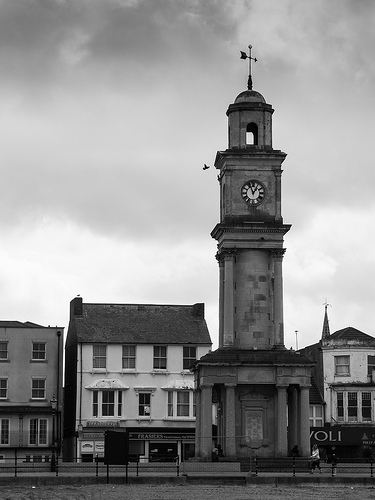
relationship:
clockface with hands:
[241, 177, 265, 204] [248, 184, 254, 195]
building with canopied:
[65, 294, 213, 462] [188, 288, 206, 327]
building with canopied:
[65, 294, 213, 462] [65, 291, 88, 323]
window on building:
[331, 388, 374, 426] [301, 298, 373, 453]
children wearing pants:
[310, 444, 324, 474] [312, 458, 322, 469]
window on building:
[93, 344, 107, 368] [65, 295, 211, 460]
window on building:
[135, 389, 153, 420] [65, 295, 211, 460]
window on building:
[181, 341, 198, 371] [65, 295, 211, 460]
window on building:
[90, 390, 121, 416] [65, 295, 211, 460]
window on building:
[152, 345, 176, 373] [65, 295, 211, 460]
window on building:
[160, 373, 200, 428] [65, 299, 241, 455]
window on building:
[84, 337, 116, 370] [0, 320, 62, 461]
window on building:
[0, 342, 7, 359] [0, 320, 62, 461]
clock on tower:
[238, 180, 279, 212] [192, 80, 325, 473]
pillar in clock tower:
[273, 384, 291, 457] [193, 46, 310, 471]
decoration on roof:
[316, 297, 339, 337] [310, 313, 373, 354]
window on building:
[155, 346, 167, 371] [65, 295, 211, 460]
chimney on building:
[64, 294, 104, 331] [65, 295, 211, 460]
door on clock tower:
[242, 396, 267, 446] [190, 46, 318, 472]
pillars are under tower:
[194, 381, 318, 466] [214, 78, 291, 344]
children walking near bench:
[310, 444, 324, 474] [239, 454, 324, 483]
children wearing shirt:
[310, 444, 324, 474] [312, 448, 320, 462]